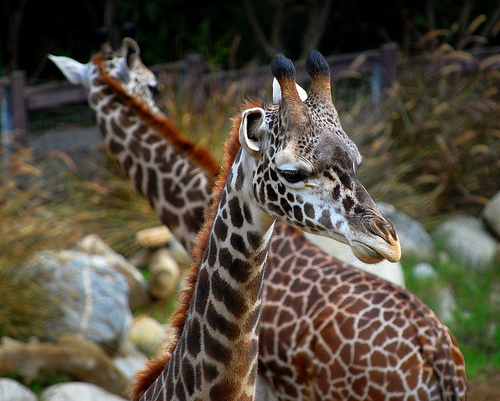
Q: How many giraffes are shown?
A: Two.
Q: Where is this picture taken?
A: A zoo.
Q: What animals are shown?
A: Giraffes.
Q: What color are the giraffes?
A: Brown and white.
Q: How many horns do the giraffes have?
A: Two.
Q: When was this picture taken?
A: Daytime.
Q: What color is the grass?
A: Green.